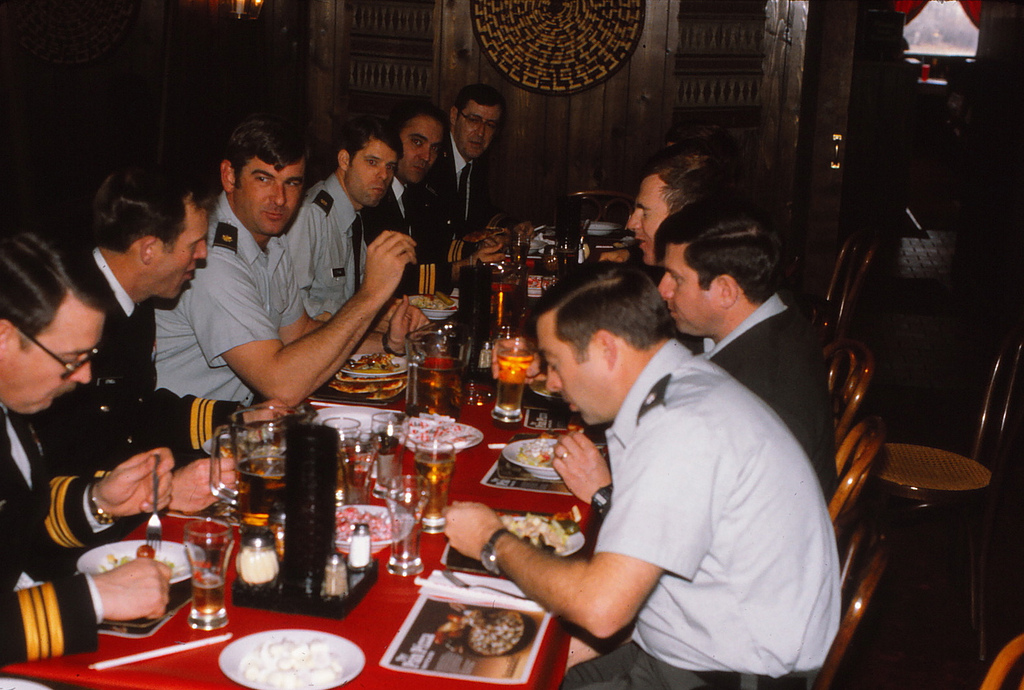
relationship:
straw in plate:
[86, 627, 230, 682] [0, 220, 655, 690]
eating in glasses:
[441, 271, 838, 690] [7, 307, 106, 388]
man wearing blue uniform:
[0, 230, 173, 670] [75, 156, 278, 493]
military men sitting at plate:
[9, 86, 532, 661] [0, 220, 655, 690]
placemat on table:
[357, 500, 569, 688] [18, 159, 721, 687]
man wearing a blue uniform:
[9, 238, 187, 662] [29, 244, 242, 476]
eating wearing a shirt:
[441, 271, 838, 690] [575, 334, 841, 661]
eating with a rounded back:
[441, 271, 838, 690] [609, 348, 844, 684]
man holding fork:
[9, 238, 187, 662] [126, 448, 175, 553]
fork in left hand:
[126, 448, 175, 553] [435, 496, 505, 559]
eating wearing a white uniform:
[441, 271, 838, 690] [145, 176, 323, 395]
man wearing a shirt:
[163, 143, 375, 397] [588, 340, 839, 678]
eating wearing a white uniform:
[441, 271, 838, 690] [285, 112, 400, 331]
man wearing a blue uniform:
[0, 230, 173, 670] [48, 149, 263, 485]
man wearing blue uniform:
[26, 163, 290, 501] [67, 169, 233, 448]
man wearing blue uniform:
[0, 230, 173, 670] [367, 90, 437, 265]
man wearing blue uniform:
[0, 230, 173, 670] [438, 80, 511, 223]